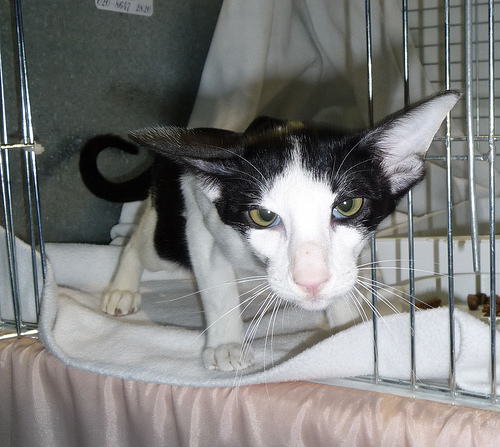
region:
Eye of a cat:
[241, 203, 281, 233]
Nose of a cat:
[284, 232, 334, 297]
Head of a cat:
[116, 78, 469, 316]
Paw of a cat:
[197, 338, 259, 376]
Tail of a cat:
[61, 116, 142, 208]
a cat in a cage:
[94, 54, 493, 437]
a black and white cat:
[108, 137, 392, 404]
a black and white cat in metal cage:
[39, 120, 401, 354]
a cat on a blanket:
[94, 133, 486, 334]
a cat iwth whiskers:
[219, 190, 357, 333]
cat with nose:
[289, 213, 329, 294]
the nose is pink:
[294, 247, 329, 293]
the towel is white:
[122, 301, 359, 368]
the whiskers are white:
[219, 240, 414, 339]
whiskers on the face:
[225, 260, 412, 335]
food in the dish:
[412, 260, 496, 332]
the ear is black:
[170, 119, 275, 176]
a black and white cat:
[119, 116, 406, 439]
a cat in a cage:
[29, 83, 439, 443]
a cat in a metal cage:
[116, 90, 494, 437]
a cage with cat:
[57, 49, 495, 400]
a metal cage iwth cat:
[89, 63, 493, 403]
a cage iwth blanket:
[53, 199, 414, 437]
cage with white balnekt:
[47, 235, 382, 442]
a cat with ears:
[104, 63, 479, 355]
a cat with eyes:
[244, 154, 352, 251]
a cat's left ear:
[365, 90, 462, 202]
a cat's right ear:
[127, 123, 244, 180]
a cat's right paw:
[199, 340, 254, 370]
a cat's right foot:
[102, 288, 142, 316]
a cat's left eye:
[330, 195, 364, 220]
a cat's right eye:
[242, 203, 281, 225]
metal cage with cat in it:
[0, 0, 497, 408]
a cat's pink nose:
[293, 263, 330, 292]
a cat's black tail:
[79, 131, 158, 203]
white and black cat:
[80, 89, 462, 369]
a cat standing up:
[115, 126, 442, 383]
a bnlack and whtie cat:
[119, 115, 346, 355]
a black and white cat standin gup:
[90, 83, 467, 385]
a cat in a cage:
[162, 100, 460, 369]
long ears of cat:
[118, 82, 473, 199]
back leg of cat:
[93, 223, 160, 325]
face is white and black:
[217, 118, 392, 310]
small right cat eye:
[331, 188, 368, 218]